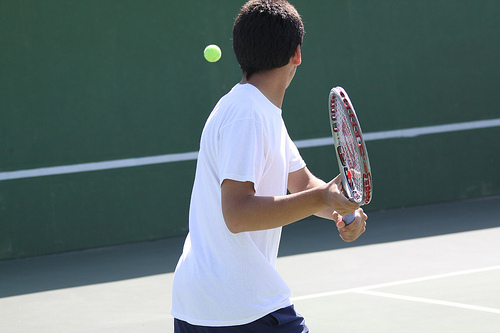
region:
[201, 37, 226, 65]
a tennis ball in the air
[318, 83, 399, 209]
a tennis racket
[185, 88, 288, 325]
a white t shirt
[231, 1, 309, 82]
the head of a person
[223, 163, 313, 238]
the arm of a person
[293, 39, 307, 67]
the ear of a person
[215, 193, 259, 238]
the elbow of a person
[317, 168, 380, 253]
hands holding a tennis racket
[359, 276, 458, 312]
the white line of a tennis court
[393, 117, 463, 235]
a tennis net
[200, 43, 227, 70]
A small green tennis ball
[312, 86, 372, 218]
A white and red tennis racket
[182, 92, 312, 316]
A white tee shirt on the man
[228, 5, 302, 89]
Short black hair on the man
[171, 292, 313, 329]
Blue shorts on the man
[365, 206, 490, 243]
Shadow of the wall on the ground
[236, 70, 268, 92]
Short neck hair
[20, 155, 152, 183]
A white line on the wall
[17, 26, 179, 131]
A large green wall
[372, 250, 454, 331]
White lines on the court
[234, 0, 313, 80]
A head of a young man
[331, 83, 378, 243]
A grey and red tennis racket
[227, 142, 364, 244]
Hands holding a tennis Racket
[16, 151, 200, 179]
A tennis rope separator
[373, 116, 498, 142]
A tennis rope separator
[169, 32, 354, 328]
A boy playing tennis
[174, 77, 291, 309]
A nice white Tshirt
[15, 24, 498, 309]
A complete tennis court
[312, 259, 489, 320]
A marked tennis field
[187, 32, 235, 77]
a yellow tennis ball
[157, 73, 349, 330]
a white tee shirt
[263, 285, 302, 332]
blue pocket of pants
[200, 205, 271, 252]
an elbow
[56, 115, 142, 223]
a white stripe on a green background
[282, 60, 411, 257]
red and silver tennis racket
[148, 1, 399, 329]
a young boy playing tennis on the wall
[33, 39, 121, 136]
a green wall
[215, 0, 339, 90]
young boy with dark brown hair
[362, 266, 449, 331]
lines on the tennis court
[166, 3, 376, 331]
Tennis player holding racquet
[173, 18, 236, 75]
A green tennis ball in the air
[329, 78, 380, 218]
Tennis racquet is red and white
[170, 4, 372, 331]
Tennis player swinging racquet to hit ball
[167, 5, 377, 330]
Tennis player is wearing a white shirt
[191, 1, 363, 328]
Tennis player has dark hair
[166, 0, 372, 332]
Tennis player has short hair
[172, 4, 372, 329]
Tennis player is wearing blue and white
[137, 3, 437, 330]
Tennis player standing on court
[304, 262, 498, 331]
White lines are on tennis court